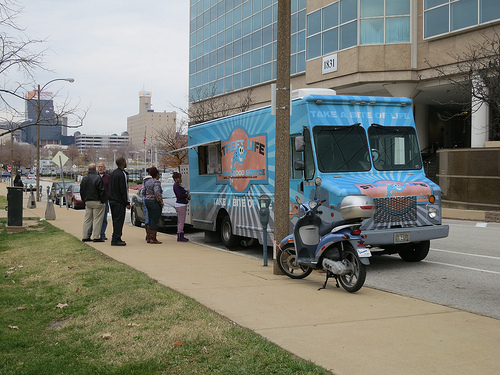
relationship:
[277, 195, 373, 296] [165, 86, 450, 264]
motor scooter next to food truck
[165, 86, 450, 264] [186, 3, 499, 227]
food truck next to building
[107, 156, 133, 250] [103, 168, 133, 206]
man wears jacket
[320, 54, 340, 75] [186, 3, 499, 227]
sign on building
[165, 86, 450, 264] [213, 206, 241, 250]
food truck has left rear tire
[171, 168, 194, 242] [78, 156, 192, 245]
person in line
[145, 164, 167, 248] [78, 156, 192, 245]
woman in line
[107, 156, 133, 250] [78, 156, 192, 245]
man in line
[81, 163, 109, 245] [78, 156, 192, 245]
man in line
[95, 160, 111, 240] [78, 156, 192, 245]
man in line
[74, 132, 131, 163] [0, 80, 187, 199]
building in distance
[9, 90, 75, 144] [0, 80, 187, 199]
building in distance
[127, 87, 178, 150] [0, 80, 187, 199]
building in distance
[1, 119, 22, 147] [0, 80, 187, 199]
building in distance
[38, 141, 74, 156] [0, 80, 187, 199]
building in distance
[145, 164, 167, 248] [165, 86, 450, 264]
woman at food truck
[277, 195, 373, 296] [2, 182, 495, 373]
motor scooter on sidewalk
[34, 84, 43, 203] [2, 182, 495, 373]
lamp post on sidewalk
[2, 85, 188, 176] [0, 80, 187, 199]
city in distance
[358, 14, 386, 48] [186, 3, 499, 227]
window in building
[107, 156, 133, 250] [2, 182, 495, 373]
man on sidewalk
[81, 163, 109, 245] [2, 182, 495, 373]
man on sidewalk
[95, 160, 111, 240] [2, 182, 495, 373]
man on sidewalk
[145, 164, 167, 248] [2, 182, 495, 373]
woman on sidewalk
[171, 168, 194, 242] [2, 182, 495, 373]
person on sidewalk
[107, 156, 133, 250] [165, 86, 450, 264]
man waiting for food truck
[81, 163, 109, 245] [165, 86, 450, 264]
man waiting for food truck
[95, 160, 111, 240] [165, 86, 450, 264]
man waiting for food truck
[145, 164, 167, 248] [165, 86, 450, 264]
woman waiting for food truck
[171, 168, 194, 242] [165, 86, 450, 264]
person waiting for food truck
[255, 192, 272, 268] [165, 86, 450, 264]
parking meter near food truck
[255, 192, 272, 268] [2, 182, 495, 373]
parking meter on sidewalk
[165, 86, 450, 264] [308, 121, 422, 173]
food truck has windshield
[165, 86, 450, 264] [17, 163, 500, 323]
food truck on road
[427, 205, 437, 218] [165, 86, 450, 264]
headlight on food truck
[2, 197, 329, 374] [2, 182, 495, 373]
grass next to sidewalk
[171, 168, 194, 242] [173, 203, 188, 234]
person wears pants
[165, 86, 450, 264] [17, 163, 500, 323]
food truck in road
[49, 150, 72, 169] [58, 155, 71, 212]
road sign on post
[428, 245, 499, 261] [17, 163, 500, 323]
line on road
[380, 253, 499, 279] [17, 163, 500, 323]
line on road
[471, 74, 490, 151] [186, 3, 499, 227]
pillar in building